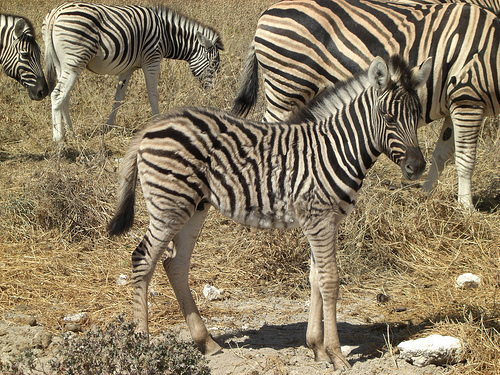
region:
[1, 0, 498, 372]
The ground has dry hay and white rocks.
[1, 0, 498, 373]
Several zebras are standing on dry terrain.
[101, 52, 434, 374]
Zebra has black and white stripes.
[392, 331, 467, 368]
White rock on ground.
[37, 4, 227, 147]
Zebra is grazing on the dead grass.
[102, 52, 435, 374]
Black and white striped zebra has perked up ears.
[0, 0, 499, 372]
Group of zebras are walking in dry field.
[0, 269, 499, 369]
White rocks are lying on the ground.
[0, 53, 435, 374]
Zebra is standing next to dead shrubbery.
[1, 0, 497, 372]
zebras standing on the grass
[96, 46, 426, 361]
black and white stripes on the body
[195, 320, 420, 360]
shadow on the ground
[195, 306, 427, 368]
shadow from the zebra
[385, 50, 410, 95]
hair between the ears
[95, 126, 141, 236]
hair on the tail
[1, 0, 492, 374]
herd of zebras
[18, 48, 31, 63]
black eye on the side of the face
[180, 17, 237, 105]
head is bent down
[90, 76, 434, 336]
a small baby zebra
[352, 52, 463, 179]
the head of a baby zebra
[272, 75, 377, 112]
the mane of a baby zebra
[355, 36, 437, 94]
the ears of a baby zebra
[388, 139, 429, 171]
the nose of a baby zebra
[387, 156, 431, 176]
the snout of a baby zebra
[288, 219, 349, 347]
the front legs of a baby zebra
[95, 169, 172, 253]
the tail of a baby zebra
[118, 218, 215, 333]
the hind legs of a baby zebra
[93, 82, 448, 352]
a very tiny baby zebra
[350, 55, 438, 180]
the head of a baby zebra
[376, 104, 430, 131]
the eyes of a baby zebra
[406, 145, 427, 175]
the nose of a baby zebra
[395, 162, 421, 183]
the mouth of a baby zebra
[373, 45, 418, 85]
the mane of a baby zebra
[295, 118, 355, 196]
the stripes of a baby zebra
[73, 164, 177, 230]
the tail of a baby zebra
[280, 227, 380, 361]
the front legs of a baby zebra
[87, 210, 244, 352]
the hind legs of a baby zebra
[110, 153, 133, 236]
tail of zebra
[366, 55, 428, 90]
ear of the zebra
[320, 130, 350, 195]
white and black stripes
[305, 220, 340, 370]
front legs of zebra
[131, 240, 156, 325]
back leg of the zebra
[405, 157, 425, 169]
nose of the zebra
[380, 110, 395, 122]
eye of the zebra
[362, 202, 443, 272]
dry grasses lying on ground